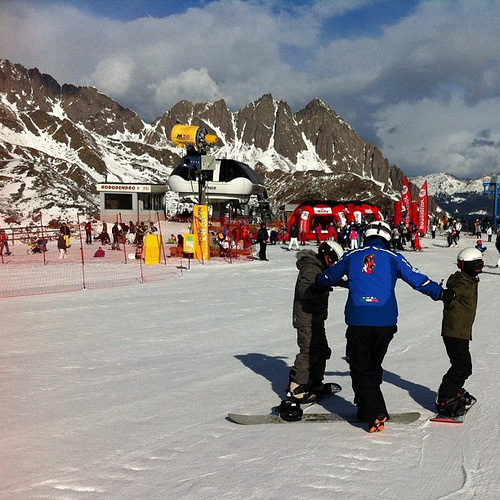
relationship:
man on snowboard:
[433, 245, 485, 419] [427, 394, 479, 426]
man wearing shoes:
[324, 220, 444, 435] [361, 410, 395, 433]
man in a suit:
[284, 223, 423, 424] [285, 252, 342, 384]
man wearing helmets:
[324, 220, 444, 435] [312, 215, 491, 272]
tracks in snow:
[309, 439, 388, 497] [419, 443, 479, 498]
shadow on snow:
[233, 350, 293, 398] [1, 300, 218, 497]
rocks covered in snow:
[28, 87, 342, 158] [234, 139, 287, 171]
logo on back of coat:
[358, 252, 392, 279] [320, 238, 444, 330]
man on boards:
[284, 240, 350, 401] [220, 376, 498, 441]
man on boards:
[328, 204, 431, 431] [220, 376, 498, 441]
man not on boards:
[434, 238, 485, 426] [220, 376, 498, 441]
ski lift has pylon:
[63, 150, 273, 270] [477, 78, 485, 232]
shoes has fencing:
[369, 410, 389, 433] [1, 216, 259, 296]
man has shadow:
[324, 220, 444, 435] [232, 339, 290, 390]